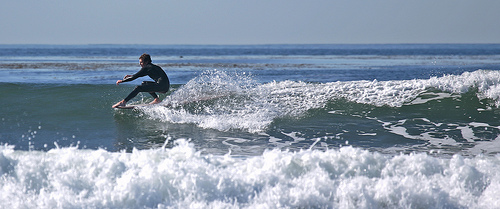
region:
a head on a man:
[136, 53, 155, 65]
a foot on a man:
[109, 100, 127, 110]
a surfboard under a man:
[114, 92, 163, 110]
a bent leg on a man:
[124, 80, 152, 97]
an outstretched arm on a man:
[129, 64, 154, 82]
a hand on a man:
[116, 76, 121, 83]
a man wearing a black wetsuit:
[119, 48, 183, 118]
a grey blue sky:
[5, 3, 496, 39]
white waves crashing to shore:
[11, 142, 485, 197]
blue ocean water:
[1, 46, 497, 150]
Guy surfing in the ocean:
[98, 45, 184, 115]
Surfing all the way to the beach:
[115, 40, 235, 135]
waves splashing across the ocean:
[55, 100, 391, 205]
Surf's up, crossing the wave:
[90, 40, 220, 140]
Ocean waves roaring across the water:
[296, 26, 471, 166]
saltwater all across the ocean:
[200, 73, 336, 201]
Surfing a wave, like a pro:
[82, 37, 202, 120]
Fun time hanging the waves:
[85, 45, 227, 151]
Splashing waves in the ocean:
[185, 57, 346, 194]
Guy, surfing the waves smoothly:
[99, 33, 256, 174]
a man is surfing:
[36, 17, 315, 207]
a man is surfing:
[77, 35, 216, 159]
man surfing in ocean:
[92, 32, 198, 132]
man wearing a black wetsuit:
[102, 41, 234, 116]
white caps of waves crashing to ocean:
[147, 149, 324, 194]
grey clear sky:
[297, 7, 415, 37]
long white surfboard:
[92, 87, 250, 118]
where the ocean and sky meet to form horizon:
[199, 28, 312, 50]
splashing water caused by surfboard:
[120, 75, 267, 133]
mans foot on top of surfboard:
[110, 48, 186, 113]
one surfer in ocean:
[95, 33, 185, 125]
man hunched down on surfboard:
[92, 36, 228, 115]